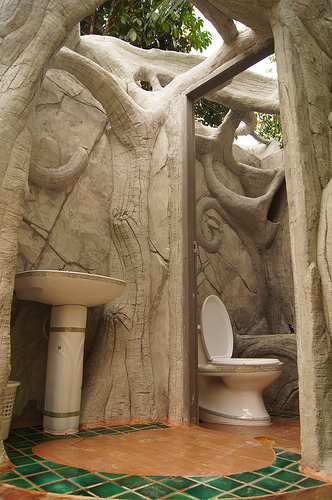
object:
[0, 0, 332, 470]
wooden trunk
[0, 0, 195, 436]
wall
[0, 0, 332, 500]
bathroom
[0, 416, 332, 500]
area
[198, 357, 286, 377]
seat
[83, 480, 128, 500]
tiles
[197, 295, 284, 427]
toilet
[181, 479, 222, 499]
tile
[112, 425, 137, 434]
tile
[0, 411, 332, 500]
floor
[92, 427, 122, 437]
tile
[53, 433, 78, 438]
tile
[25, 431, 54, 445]
tile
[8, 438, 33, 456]
tile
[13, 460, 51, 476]
tile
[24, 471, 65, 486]
tile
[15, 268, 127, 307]
sink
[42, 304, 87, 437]
pedestal